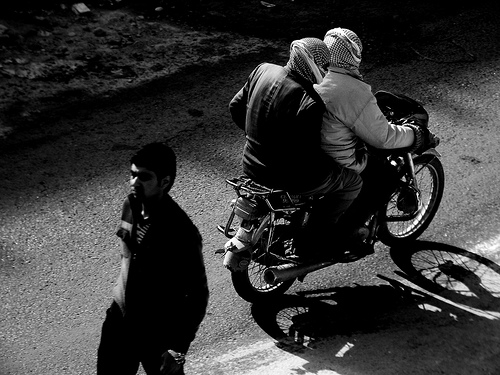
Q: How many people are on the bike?
A: 2.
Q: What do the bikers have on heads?
A: Helmets.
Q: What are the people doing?
A: Riding motorcycle.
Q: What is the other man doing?
A: Walking.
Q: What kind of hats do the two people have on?
A: Masks.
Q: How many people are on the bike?
A: Two.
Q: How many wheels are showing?
A: 2.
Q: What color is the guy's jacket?
A: Black.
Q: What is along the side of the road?
A: Dirt.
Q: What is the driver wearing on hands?
A: Gloves.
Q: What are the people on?
A: Motorcycle.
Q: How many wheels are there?
A: Two.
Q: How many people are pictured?
A: Three.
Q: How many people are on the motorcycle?
A: Two.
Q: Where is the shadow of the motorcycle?
A: Right of motorcycle.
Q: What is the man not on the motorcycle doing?
A: Standing.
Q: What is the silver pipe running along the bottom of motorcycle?
A: Exhaust pipe.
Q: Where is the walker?
A: Behind motorcycle.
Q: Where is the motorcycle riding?
A: Street.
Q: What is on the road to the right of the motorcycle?
A: Shadow.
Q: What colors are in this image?
A: Black and white.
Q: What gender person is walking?
A: Male.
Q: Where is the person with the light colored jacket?
A: Front of motorcycle.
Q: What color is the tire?
A: Black.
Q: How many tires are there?
A: Two.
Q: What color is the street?
A: Gray.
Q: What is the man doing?
A: Walking.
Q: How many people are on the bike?
A: Two.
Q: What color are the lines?
A: White.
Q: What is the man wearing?
A: A jacket.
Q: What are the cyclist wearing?
A: Head Wraps.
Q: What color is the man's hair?
A: Black.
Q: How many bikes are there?
A: One.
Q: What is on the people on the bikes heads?
A: Scarves.